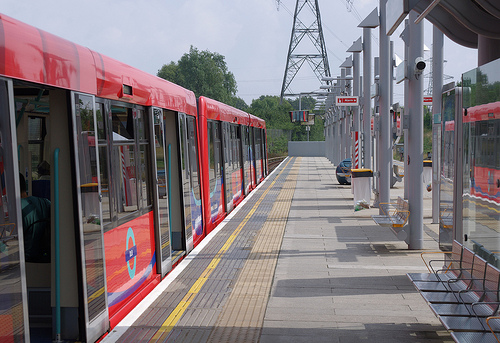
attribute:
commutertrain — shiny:
[3, 20, 270, 341]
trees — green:
[157, 50, 319, 134]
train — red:
[2, 18, 275, 337]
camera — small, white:
[405, 54, 426, 83]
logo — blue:
[94, 211, 167, 321]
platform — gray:
[96, 156, 499, 341]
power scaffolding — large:
[277, 1, 343, 118]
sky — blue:
[147, 10, 187, 30]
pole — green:
[47, 145, 62, 342]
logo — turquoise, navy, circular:
[124, 227, 141, 278]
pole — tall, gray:
[269, 0, 327, 111]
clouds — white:
[222, 13, 321, 55]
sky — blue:
[28, 0, 428, 98]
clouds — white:
[218, 16, 248, 46]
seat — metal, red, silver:
[407, 240, 466, 282]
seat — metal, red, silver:
[415, 247, 475, 292]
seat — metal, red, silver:
[416, 253, 488, 303]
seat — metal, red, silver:
[423, 260, 498, 317]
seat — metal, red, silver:
[421, 299, 498, 331]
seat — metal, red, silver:
[434, 326, 499, 341]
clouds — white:
[103, 26, 124, 41]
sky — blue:
[0, 2, 477, 104]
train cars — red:
[1, 14, 270, 341]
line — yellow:
[148, 157, 293, 342]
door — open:
[7, 79, 77, 342]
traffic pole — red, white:
[348, 127, 370, 172]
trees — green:
[209, 59, 377, 147]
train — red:
[88, 66, 198, 234]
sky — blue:
[0, 3, 482, 115]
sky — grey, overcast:
[6, 2, 285, 43]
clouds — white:
[121, 21, 286, 43]